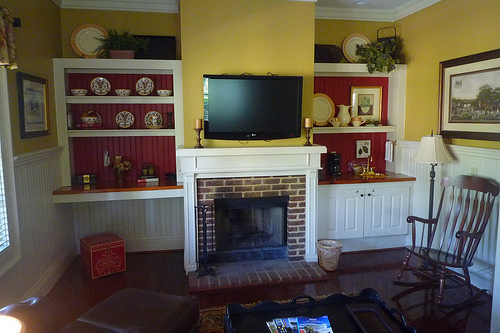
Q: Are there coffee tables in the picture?
A: Yes, there is a coffee table.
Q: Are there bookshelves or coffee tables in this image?
A: Yes, there is a coffee table.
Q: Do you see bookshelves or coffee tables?
A: Yes, there is a coffee table.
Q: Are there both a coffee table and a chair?
A: Yes, there are both a coffee table and a chair.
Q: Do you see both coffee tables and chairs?
A: Yes, there are both a coffee table and chairs.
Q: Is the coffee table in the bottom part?
A: Yes, the coffee table is in the bottom of the image.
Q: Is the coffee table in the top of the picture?
A: No, the coffee table is in the bottom of the image.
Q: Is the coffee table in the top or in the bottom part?
A: The coffee table is in the bottom of the image.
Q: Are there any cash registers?
A: No, there are no cash registers.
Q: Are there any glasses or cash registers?
A: No, there are no cash registers or glasses.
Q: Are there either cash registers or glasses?
A: No, there are no cash registers or glasses.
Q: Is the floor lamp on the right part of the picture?
A: Yes, the floor lamp is on the right of the image.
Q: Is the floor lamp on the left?
A: No, the floor lamp is on the right of the image.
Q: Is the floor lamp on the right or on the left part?
A: The floor lamp is on the right of the image.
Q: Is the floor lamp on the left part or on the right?
A: The floor lamp is on the right of the image.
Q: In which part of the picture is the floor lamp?
A: The floor lamp is on the right of the image.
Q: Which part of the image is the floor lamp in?
A: The floor lamp is on the right of the image.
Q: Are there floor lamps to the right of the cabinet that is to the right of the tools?
A: Yes, there is a floor lamp to the right of the cabinet.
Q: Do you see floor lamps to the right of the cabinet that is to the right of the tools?
A: Yes, there is a floor lamp to the right of the cabinet.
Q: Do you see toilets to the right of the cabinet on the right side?
A: No, there is a floor lamp to the right of the cabinet.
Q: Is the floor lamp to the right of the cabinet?
A: Yes, the floor lamp is to the right of the cabinet.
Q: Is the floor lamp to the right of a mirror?
A: No, the floor lamp is to the right of the cabinet.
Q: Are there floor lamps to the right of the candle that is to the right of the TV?
A: Yes, there is a floor lamp to the right of the candle.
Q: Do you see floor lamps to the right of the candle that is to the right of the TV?
A: Yes, there is a floor lamp to the right of the candle.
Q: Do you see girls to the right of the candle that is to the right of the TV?
A: No, there is a floor lamp to the right of the candle.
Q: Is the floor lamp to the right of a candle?
A: Yes, the floor lamp is to the right of a candle.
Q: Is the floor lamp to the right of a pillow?
A: No, the floor lamp is to the right of a candle.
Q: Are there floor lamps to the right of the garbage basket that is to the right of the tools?
A: Yes, there is a floor lamp to the right of the waste basket.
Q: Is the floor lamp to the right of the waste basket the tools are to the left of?
A: Yes, the floor lamp is to the right of the waste basket.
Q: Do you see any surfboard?
A: No, there are no surfboards.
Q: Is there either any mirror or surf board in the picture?
A: No, there are no surfboards or mirrors.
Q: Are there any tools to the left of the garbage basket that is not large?
A: Yes, there are tools to the left of the garbage basket.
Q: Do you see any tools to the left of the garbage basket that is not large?
A: Yes, there are tools to the left of the garbage basket.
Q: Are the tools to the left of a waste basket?
A: Yes, the tools are to the left of a waste basket.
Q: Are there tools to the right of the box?
A: Yes, there are tools to the right of the box.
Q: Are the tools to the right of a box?
A: Yes, the tools are to the right of a box.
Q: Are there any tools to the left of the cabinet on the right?
A: Yes, there are tools to the left of the cabinet.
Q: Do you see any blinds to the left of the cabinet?
A: No, there are tools to the left of the cabinet.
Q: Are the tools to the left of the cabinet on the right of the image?
A: Yes, the tools are to the left of the cabinet.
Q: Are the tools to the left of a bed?
A: No, the tools are to the left of the cabinet.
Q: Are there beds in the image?
A: No, there are no beds.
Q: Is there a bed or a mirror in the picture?
A: No, there are no beds or mirrors.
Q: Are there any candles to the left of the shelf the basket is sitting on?
A: Yes, there is a candle to the left of the shelf.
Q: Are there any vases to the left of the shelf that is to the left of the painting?
A: No, there is a candle to the left of the shelf.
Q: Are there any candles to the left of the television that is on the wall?
A: Yes, there is a candle to the left of the television.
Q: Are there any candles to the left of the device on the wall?
A: Yes, there is a candle to the left of the television.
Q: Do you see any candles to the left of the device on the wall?
A: Yes, there is a candle to the left of the television.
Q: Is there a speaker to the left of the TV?
A: No, there is a candle to the left of the TV.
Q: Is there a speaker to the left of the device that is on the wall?
A: No, there is a candle to the left of the TV.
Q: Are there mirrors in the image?
A: No, there are no mirrors.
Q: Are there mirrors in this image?
A: No, there are no mirrors.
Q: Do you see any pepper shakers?
A: No, there are no pepper shakers.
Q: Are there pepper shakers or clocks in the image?
A: No, there are no pepper shakers or clocks.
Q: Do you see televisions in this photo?
A: Yes, there is a television.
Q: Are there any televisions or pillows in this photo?
A: Yes, there is a television.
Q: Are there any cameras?
A: No, there are no cameras.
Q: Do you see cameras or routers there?
A: No, there are no cameras or routers.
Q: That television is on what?
A: The television is on the wall.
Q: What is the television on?
A: The television is on the wall.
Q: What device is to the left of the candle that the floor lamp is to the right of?
A: The device is a television.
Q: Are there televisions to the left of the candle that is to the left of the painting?
A: Yes, there is a television to the left of the candle.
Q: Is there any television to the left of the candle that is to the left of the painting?
A: Yes, there is a television to the left of the candle.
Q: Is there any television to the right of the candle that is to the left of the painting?
A: No, the television is to the left of the candle.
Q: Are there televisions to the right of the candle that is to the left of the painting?
A: No, the television is to the left of the candle.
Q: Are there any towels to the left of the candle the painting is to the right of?
A: No, there is a television to the left of the candle.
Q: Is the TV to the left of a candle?
A: Yes, the TV is to the left of a candle.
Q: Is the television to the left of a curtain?
A: No, the television is to the left of a candle.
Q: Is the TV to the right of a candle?
A: No, the TV is to the left of a candle.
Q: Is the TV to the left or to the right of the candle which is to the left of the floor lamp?
A: The TV is to the left of the candle.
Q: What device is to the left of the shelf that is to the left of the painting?
A: The device is a television.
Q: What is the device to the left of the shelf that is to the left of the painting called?
A: The device is a television.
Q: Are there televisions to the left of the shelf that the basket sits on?
A: Yes, there is a television to the left of the shelf.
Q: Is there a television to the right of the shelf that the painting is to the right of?
A: No, the television is to the left of the shelf.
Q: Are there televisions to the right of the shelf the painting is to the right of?
A: No, the television is to the left of the shelf.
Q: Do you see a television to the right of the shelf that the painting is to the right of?
A: No, the television is to the left of the shelf.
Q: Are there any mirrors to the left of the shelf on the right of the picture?
A: No, there is a television to the left of the shelf.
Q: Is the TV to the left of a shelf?
A: Yes, the TV is to the left of a shelf.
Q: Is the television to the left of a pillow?
A: No, the television is to the left of a shelf.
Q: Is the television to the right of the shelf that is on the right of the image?
A: No, the television is to the left of the shelf.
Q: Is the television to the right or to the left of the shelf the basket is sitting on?
A: The television is to the left of the shelf.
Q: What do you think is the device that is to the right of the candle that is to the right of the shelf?
A: The device is a television.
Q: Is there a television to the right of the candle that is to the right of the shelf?
A: Yes, there is a television to the right of the candle.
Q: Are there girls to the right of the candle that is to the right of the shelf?
A: No, there is a television to the right of the candle.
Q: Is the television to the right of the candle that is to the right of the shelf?
A: Yes, the television is to the right of the candle.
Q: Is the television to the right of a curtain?
A: No, the television is to the right of the candle.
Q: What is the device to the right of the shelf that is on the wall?
A: The device is a television.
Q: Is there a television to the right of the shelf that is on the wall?
A: Yes, there is a television to the right of the shelf.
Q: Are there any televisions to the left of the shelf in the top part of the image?
A: No, the television is to the right of the shelf.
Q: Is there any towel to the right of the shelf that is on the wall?
A: No, there is a television to the right of the shelf.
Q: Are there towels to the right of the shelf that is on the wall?
A: No, there is a television to the right of the shelf.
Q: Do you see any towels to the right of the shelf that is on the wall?
A: No, there is a television to the right of the shelf.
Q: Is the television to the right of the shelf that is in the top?
A: Yes, the television is to the right of the shelf.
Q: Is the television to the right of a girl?
A: No, the television is to the right of the shelf.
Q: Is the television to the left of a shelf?
A: No, the television is to the right of a shelf.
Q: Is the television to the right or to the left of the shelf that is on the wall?
A: The television is to the right of the shelf.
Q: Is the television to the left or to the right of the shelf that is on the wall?
A: The television is to the right of the shelf.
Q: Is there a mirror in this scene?
A: No, there are no mirrors.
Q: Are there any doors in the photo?
A: Yes, there is a door.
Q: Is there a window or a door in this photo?
A: Yes, there is a door.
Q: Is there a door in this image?
A: Yes, there is a door.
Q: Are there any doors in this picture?
A: Yes, there is a door.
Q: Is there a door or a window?
A: Yes, there is a door.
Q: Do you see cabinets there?
A: Yes, there is a cabinet.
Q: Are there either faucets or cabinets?
A: Yes, there is a cabinet.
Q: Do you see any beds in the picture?
A: No, there are no beds.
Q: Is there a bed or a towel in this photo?
A: No, there are no beds or towels.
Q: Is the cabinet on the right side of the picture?
A: Yes, the cabinet is on the right of the image.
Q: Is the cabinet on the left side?
A: No, the cabinet is on the right of the image.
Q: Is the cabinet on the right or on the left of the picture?
A: The cabinet is on the right of the image.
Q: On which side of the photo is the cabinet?
A: The cabinet is on the right of the image.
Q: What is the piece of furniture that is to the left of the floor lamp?
A: The piece of furniture is a cabinet.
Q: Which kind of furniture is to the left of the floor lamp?
A: The piece of furniture is a cabinet.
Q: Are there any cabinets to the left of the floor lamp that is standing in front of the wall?
A: Yes, there is a cabinet to the left of the floor lamp.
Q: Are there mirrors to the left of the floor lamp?
A: No, there is a cabinet to the left of the floor lamp.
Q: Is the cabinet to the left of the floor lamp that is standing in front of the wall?
A: Yes, the cabinet is to the left of the floor lamp.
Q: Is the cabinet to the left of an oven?
A: No, the cabinet is to the left of the floor lamp.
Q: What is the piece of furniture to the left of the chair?
A: The piece of furniture is a cabinet.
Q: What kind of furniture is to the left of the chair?
A: The piece of furniture is a cabinet.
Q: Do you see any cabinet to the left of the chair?
A: Yes, there is a cabinet to the left of the chair.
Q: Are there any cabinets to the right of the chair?
A: No, the cabinet is to the left of the chair.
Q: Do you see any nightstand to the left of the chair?
A: No, there is a cabinet to the left of the chair.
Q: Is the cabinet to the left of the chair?
A: Yes, the cabinet is to the left of the chair.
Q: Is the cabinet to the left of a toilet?
A: No, the cabinet is to the left of the chair.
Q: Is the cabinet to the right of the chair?
A: No, the cabinet is to the left of the chair.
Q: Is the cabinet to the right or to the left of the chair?
A: The cabinet is to the left of the chair.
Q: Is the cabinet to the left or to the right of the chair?
A: The cabinet is to the left of the chair.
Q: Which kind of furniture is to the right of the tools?
A: The piece of furniture is a cabinet.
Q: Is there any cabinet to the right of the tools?
A: Yes, there is a cabinet to the right of the tools.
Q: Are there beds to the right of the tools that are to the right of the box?
A: No, there is a cabinet to the right of the tools.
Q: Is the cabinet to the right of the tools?
A: Yes, the cabinet is to the right of the tools.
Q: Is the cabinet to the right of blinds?
A: No, the cabinet is to the right of the tools.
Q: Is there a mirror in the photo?
A: No, there are no mirrors.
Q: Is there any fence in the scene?
A: No, there are no fences.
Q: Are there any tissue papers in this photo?
A: No, there are no tissue papers.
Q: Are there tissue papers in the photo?
A: No, there are no tissue papers.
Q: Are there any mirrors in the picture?
A: No, there are no mirrors.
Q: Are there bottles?
A: No, there are no bottles.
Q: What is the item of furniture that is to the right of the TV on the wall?
A: The piece of furniture is a shelf.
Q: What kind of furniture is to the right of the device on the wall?
A: The piece of furniture is a shelf.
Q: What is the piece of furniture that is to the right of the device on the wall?
A: The piece of furniture is a shelf.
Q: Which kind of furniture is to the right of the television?
A: The piece of furniture is a shelf.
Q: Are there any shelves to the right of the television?
A: Yes, there is a shelf to the right of the television.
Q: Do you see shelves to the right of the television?
A: Yes, there is a shelf to the right of the television.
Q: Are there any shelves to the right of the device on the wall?
A: Yes, there is a shelf to the right of the television.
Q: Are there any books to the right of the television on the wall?
A: No, there is a shelf to the right of the television.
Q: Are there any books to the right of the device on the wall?
A: No, there is a shelf to the right of the television.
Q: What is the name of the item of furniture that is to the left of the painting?
A: The piece of furniture is a shelf.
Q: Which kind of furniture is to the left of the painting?
A: The piece of furniture is a shelf.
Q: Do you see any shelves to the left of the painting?
A: Yes, there is a shelf to the left of the painting.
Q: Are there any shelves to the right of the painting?
A: No, the shelf is to the left of the painting.